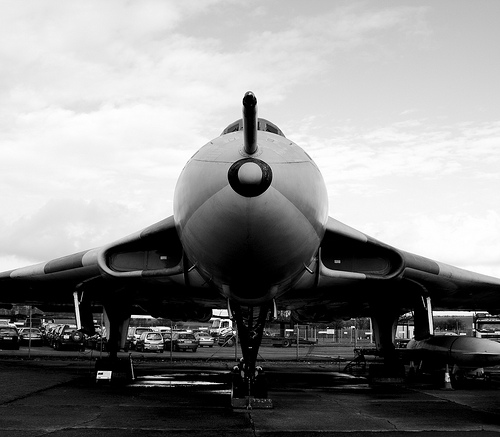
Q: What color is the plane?
A: Black, white, and Grey.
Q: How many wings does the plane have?
A: 2.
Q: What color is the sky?
A: Grey.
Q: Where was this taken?
A: Airport.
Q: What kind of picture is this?
A: Black and white.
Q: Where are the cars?
A: Behind the fence.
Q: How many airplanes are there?
A: 1.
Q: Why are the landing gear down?
A: Plane is idle.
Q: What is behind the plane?
A: Fence.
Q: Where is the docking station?
A: Under the plane.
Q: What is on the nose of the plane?
A: Metal bar.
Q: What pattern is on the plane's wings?
A: Stripes.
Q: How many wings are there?
A: 2.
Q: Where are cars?
A: Parked in parking lot.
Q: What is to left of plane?
A: A wing.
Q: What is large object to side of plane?
A: Wing.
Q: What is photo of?
A: Plane in black and white.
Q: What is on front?
A: The nose.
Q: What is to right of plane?
A: Wing.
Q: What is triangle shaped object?
A: Left wing.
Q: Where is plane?
A: On tarmac.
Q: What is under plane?
A: Wheels.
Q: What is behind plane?
A: Sky.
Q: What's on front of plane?
A: Propeller.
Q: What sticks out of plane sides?
A: Wings.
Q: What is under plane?
A: Water.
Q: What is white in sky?
A: Clouds.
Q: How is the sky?
A: Cloudy.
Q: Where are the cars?
A: Behind the plan.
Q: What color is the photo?
A: Black and white.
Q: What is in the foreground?
A: An airplane.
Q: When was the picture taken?
A: Daytime.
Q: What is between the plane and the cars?
A: A fence.